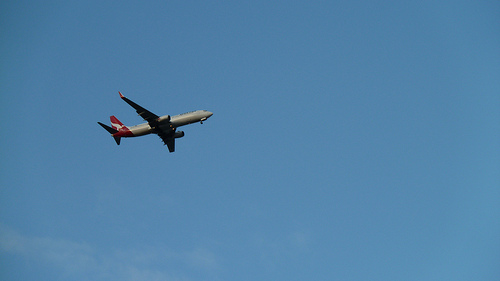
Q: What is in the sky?
A: Plane.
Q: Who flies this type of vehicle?
A: Pilot.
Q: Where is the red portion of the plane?
A: Tail.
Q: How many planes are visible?
A: One.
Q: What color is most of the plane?
A: Gray.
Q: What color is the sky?
A: Blue.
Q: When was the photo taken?
A: Daytime.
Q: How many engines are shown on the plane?
A: Two.